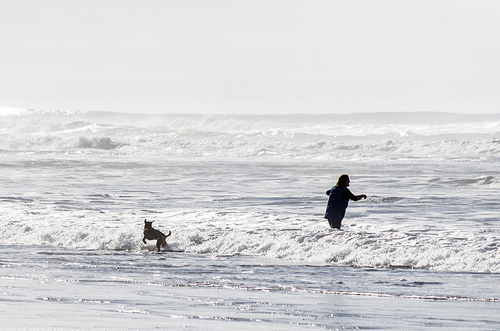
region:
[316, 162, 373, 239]
Person in the beach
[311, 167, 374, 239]
Person wears black cloths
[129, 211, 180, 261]
Dog jumps in the water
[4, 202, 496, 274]
Waves rolling in the sand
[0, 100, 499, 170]
Water is choppy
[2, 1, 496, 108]
Sky is white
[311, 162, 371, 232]
Person has extended arms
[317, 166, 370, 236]
Person has short hair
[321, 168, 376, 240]
Person has legs on the water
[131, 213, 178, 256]
Dog is jumping in the water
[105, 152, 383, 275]
person and dog in the ocean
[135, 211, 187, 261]
dog jumping in front of wave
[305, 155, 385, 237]
person standing in water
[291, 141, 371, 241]
water thigh deep on person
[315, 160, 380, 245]
person turned toward the ocean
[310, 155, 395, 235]
arms raised and elbows bent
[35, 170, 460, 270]
line of wave by dog and person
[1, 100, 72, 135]
curve of wave glistening in the sun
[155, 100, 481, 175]
other lines of waves coming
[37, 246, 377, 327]
shining edges of shallow water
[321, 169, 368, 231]
Person knee high in ocean water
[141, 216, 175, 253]
Dog jumping in the water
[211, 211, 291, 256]
waves in the ocean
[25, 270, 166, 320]
water on the shore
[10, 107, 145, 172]
Large waves in the ocean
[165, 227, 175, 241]
Tail of a dog in the ocean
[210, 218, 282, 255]
waves in the water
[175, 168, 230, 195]
ripples in the water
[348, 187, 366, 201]
an extended right arm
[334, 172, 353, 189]
Head of a person in the water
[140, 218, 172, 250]
A dog playing in the water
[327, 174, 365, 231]
A person in the water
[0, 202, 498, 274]
A wave moving toward shore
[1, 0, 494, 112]
A gray sky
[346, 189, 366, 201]
A person's arm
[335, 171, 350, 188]
A person's head from behind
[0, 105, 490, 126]
A wave moving toward shore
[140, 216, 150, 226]
A dog's head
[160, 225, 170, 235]
A dog's tail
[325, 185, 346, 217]
A person's torso from behind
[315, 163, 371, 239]
Woman stand in the sea water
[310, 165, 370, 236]
Woman has black cloths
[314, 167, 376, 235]
Woman has extended arms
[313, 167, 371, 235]
Feet of woman are in the sea water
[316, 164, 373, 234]
Woman facing forward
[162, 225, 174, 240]
Tail of dog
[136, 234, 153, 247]
Front feet of dog is up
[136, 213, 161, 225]
Ears of dog are pointy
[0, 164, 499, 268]
Woman and dog in a wave